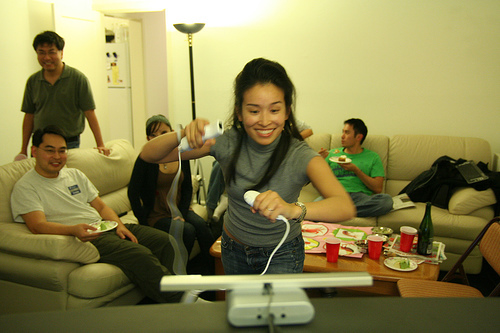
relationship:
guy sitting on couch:
[15, 119, 196, 302] [3, 225, 119, 307]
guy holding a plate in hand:
[324, 147, 359, 172] [68, 222, 101, 245]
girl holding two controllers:
[140, 57, 356, 274] [163, 110, 323, 254]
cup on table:
[400, 226, 418, 252] [313, 228, 436, 287]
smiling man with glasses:
[35, 139, 82, 177] [37, 141, 68, 156]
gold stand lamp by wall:
[172, 15, 216, 135] [163, 21, 228, 113]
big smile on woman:
[237, 103, 297, 146] [222, 56, 314, 275]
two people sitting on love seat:
[14, 107, 206, 293] [5, 140, 195, 284]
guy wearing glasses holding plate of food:
[8, 127, 209, 304] [321, 143, 361, 178]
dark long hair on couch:
[226, 57, 304, 192] [0, 133, 500, 313]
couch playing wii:
[0, 133, 500, 313] [153, 275, 373, 289]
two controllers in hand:
[178, 121, 285, 222] [181, 122, 204, 140]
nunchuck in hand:
[248, 190, 258, 197] [257, 191, 284, 216]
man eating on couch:
[312, 105, 396, 214] [392, 131, 439, 158]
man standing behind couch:
[15, 26, 124, 171] [86, 155, 104, 167]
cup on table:
[324, 239, 338, 260] [372, 266, 381, 269]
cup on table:
[364, 237, 385, 258] [372, 266, 381, 269]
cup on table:
[395, 230, 416, 250] [372, 266, 381, 269]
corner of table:
[421, 235, 448, 253] [344, 260, 364, 267]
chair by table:
[437, 262, 477, 278] [344, 260, 364, 267]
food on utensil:
[399, 260, 402, 267] [386, 257, 420, 269]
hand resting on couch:
[6, 194, 102, 264] [90, 159, 117, 173]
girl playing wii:
[135, 57, 355, 267] [155, 271, 365, 287]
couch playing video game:
[0, 133, 500, 313] [157, 275, 373, 291]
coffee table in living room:
[211, 221, 440, 296] [1, 2, 497, 327]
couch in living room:
[312, 122, 500, 276] [1, 2, 497, 327]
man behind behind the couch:
[18, 15, 119, 185] [14, 28, 120, 164]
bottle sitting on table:
[417, 202, 434, 255] [214, 187, 484, 303]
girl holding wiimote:
[140, 57, 356, 274] [179, 107, 306, 247]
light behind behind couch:
[160, 12, 215, 47] [154, 81, 478, 236]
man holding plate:
[314, 81, 401, 231] [324, 139, 365, 175]